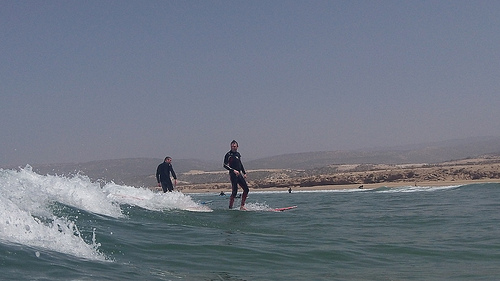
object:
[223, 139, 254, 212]
man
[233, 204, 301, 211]
surfboard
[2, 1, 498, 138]
sky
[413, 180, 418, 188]
person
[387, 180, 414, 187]
beach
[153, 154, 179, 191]
surfer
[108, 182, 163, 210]
wave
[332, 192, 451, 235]
sea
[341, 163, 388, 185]
hill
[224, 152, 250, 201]
suit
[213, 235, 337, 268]
water